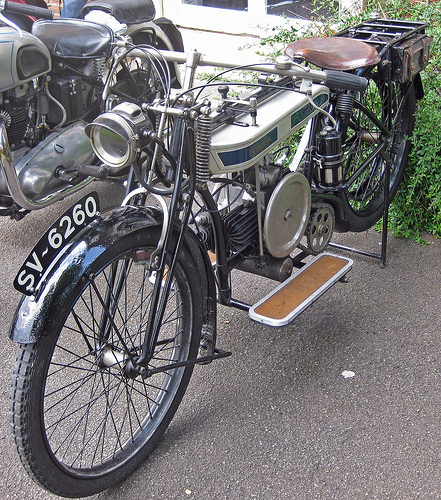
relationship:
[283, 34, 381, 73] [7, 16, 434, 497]
seat on bike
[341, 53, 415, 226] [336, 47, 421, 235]
rubber wheel on rubber wheel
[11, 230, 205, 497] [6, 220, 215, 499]
rubber wheel on rubber wheel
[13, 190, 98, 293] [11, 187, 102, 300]
numbers on license plate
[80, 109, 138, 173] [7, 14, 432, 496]
light on bike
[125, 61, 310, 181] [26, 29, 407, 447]
wire on bike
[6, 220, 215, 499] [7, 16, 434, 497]
rubber wheel on bike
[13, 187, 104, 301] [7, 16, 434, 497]
license plate on bike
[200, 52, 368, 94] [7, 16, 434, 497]
handle bar on bike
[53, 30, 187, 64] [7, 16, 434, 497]
handle bar on bike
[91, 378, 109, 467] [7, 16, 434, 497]
spoke on bike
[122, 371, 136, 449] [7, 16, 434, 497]
spoke on bike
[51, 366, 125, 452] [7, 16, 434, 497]
spoke on bike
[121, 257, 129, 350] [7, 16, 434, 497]
spoke on bike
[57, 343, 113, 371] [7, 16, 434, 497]
spoke on bike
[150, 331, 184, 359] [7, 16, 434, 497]
spoke on bike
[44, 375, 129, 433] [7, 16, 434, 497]
spoke on bike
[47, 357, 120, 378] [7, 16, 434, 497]
spoke on bike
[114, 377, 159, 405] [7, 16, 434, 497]
spoke on bike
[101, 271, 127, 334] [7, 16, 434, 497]
spoke on bike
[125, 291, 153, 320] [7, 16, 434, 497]
spoke on bike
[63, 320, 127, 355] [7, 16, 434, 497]
spoke on bike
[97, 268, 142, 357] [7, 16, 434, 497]
spoke on bike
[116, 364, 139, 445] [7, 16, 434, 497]
spoke on bike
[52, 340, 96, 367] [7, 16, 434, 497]
spoke on bike